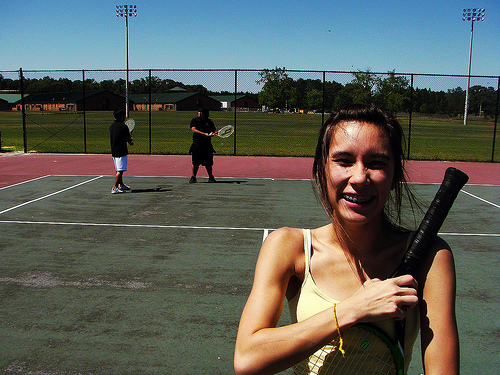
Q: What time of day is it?
A: Daytime.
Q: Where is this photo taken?
A: On a tennis court.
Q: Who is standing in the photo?
A: Men and a woman.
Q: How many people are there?
A: Three.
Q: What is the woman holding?
A: A tennis racket.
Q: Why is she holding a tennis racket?
A: Because she is getting ready to play tennis.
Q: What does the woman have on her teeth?
A: Braces.